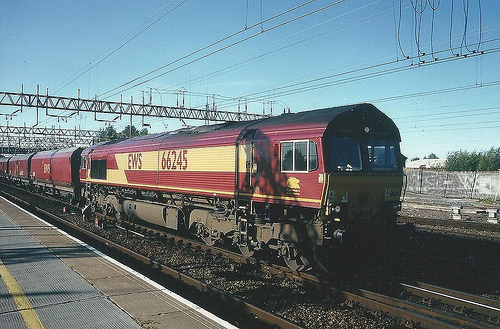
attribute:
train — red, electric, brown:
[0, 103, 417, 276]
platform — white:
[2, 195, 226, 321]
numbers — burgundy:
[161, 150, 187, 168]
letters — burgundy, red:
[128, 153, 143, 169]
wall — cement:
[400, 167, 499, 202]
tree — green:
[443, 146, 499, 170]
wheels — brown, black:
[280, 249, 308, 272]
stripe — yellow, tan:
[78, 176, 323, 205]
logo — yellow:
[115, 143, 255, 173]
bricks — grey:
[1, 207, 136, 321]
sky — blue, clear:
[1, 3, 498, 157]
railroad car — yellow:
[1, 104, 413, 275]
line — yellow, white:
[2, 258, 44, 321]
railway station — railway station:
[4, 82, 499, 320]